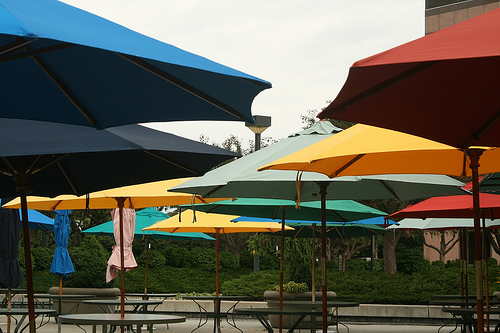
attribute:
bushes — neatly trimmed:
[12, 226, 226, 293]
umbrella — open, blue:
[0, 0, 271, 130]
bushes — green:
[132, 243, 240, 272]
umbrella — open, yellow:
[137, 197, 296, 238]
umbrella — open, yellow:
[253, 122, 497, 332]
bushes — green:
[24, 230, 499, 305]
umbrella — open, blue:
[5, 7, 294, 154]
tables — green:
[2, 274, 499, 331]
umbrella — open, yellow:
[10, 114, 242, 199]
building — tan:
[418, 5, 498, 32]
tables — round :
[18, 284, 488, 331]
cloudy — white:
[0, 0, 427, 157]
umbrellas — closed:
[196, 37, 458, 332]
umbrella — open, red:
[321, 7, 497, 138]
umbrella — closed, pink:
[103, 205, 139, 283]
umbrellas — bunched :
[90, 17, 497, 265]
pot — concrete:
[263, 280, 327, 331]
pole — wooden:
[215, 226, 222, 330]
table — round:
[54, 299, 193, 331]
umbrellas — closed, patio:
[43, 207, 143, 276]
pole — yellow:
[466, 154, 490, 326]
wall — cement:
[139, 299, 496, 321]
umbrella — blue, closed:
[49, 209, 77, 277]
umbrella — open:
[208, 191, 378, 223]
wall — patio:
[157, 258, 466, 299]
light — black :
[246, 114, 271, 136]